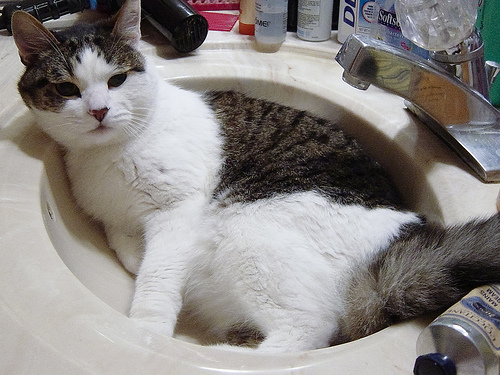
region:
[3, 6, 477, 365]
a cat in a sink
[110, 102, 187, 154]
cat's whiskers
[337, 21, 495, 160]
chrome bathroom faucet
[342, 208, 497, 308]
tail of a cat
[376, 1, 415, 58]
container of pump hand soap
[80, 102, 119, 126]
nose of a white cat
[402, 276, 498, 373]
tine tube of hand cream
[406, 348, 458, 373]
black cap on silver tube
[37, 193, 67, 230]
overflow drain hole of the sink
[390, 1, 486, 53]
clear plastic faucet handle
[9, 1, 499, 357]
Cat lying in sink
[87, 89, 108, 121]
Nose is pink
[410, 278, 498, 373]
Hand cream bottle lying flat on counter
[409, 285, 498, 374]
Hand cream bottle by cat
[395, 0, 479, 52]
Crystal knob on faucet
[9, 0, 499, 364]
Cat is awake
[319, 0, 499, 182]
Faucet is off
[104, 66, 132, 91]
Eye of cat is black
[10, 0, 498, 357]
Cat is black and white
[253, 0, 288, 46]
Plastic bottle by cat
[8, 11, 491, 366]
Black and white cat in a sink.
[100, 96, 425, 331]
Cat with fluffy fur.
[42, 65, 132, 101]
Cat with opened eyes.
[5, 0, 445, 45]
Sink surrounded by body care products.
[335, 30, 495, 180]
Chrome faucet.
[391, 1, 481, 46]
The faucet knob is clear.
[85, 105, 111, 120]
Cat's nose is pink.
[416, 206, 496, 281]
The cat's tail is black and grey.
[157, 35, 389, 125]
The sink is made of marble.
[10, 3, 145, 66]
The cat's ears are up.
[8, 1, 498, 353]
A cat in the sink.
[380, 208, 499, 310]
The tail on the counter.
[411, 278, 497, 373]
A bottle on the counter.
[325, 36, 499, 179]
The water sink facuet.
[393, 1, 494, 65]
The knob for the faucet.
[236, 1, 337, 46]
The bottom of bottles.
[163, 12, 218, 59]
vents on a hair dryer.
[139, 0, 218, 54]
The knozzle of the dryer.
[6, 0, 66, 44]
The dryer handle.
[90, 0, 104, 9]
The hair dryer switch.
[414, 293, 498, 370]
silver tube of cream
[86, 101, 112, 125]
Nose of cat in sink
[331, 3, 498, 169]
Silver faucet with clear knob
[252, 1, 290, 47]
Clear bottle with liquid in it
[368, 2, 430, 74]
Bottle of liquid hand soap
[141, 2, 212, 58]
End of hair dryer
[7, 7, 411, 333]
Cat laying in the sink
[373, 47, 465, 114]
Reflection on the water faucet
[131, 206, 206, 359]
White paw of cat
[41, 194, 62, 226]
Hold in the sink